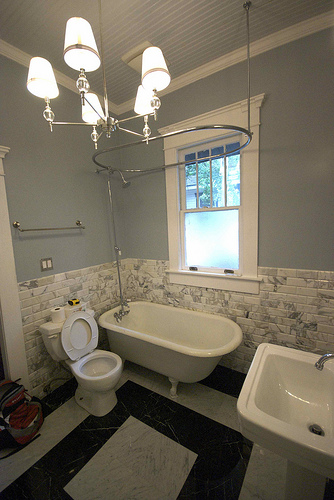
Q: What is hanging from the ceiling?
A: Lights.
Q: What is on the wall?
A: A silver towel rack.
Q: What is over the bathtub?
A: A window.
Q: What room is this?
A: Bathroom.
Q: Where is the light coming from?
A: Chandelier.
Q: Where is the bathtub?
A: Under the window.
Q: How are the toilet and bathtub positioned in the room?
A: Next to each other.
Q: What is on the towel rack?
A: Nothing.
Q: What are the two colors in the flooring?
A: Black and grey.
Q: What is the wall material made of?
A: Tiles.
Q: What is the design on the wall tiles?
A: Floral pattern.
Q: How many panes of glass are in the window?
A: Nine.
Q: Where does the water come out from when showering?
A: Showerhead.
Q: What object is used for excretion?
A: Toilet.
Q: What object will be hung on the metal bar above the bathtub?
A: Shower curtain.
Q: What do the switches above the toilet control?
A: Lights.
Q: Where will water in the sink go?
A: Drain.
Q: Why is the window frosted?
A: Privacy.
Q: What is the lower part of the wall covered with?
A: Tile.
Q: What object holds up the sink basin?
A: Pedestal.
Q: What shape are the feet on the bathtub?
A: Claws.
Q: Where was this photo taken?
A: In a bathroom.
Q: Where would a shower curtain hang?
A: On the ring above the bathtub.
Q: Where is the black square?
A: On the floor.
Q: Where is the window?
A: Above the bathtub.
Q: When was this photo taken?
A: During the daytime.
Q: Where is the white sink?
A: Across from the toilet.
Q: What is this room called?
A: A bathroom.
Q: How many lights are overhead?
A: Five.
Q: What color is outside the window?
A: Turquoise.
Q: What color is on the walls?
A: Grey.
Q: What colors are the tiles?
A: Grey and white.